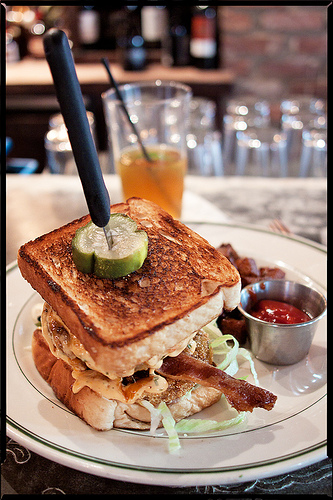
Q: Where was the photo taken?
A: Inside a place.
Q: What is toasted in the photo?
A: Bread.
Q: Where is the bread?
A: On a plate.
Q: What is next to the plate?
A: A glass.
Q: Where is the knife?
A: In the sandwich.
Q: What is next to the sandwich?
A: Ketchup.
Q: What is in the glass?
A: Dark liquid.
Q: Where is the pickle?
A: Top of sandwich.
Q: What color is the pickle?
A: Green.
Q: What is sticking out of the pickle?
A: Knife.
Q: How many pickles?
A: One.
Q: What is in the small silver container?
A: Ketchup.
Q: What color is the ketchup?
A: Red.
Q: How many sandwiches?
A: One.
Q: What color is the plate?
A: White.